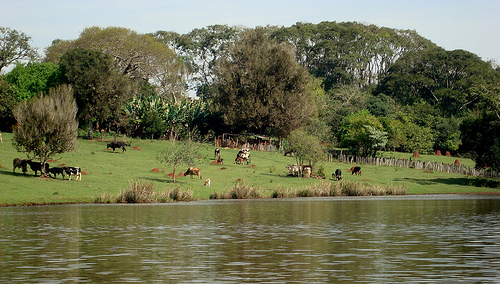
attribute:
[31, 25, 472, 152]
trees — in background, tall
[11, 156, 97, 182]
cows — standing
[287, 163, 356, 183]
cows — standing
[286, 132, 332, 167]
trees — short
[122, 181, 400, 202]
grass — tall, growing, reflecting, long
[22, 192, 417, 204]
edge — water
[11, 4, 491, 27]
sky — blue, hazy, clear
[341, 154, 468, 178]
fence — wooden, in back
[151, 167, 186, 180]
piles — brown, small, silage, reddish colored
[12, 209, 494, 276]
pond — green, calm, empty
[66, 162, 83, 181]
cow — black, white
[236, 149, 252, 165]
cow — white, black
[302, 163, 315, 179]
cow — black, white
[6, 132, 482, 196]
field — green, grassy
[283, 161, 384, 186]
cows — grazing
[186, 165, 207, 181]
cow — brown, grazing, white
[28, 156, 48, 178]
cow — black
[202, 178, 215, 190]
calf — small, brown, white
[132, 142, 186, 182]
haystacks — red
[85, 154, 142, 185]
grass — short